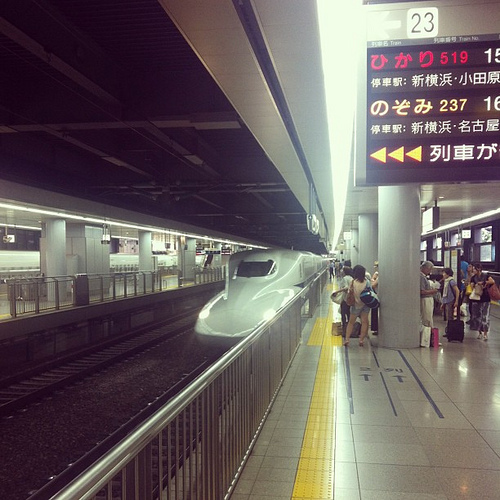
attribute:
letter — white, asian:
[429, 141, 454, 165]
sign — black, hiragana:
[358, 30, 499, 188]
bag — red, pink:
[428, 326, 439, 351]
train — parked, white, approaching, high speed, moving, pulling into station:
[189, 246, 326, 355]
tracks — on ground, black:
[1, 305, 210, 426]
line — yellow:
[293, 272, 347, 499]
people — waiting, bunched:
[332, 253, 499, 348]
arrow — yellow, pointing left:
[367, 142, 388, 169]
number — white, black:
[402, 5, 442, 41]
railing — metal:
[44, 263, 333, 499]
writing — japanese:
[367, 48, 499, 171]